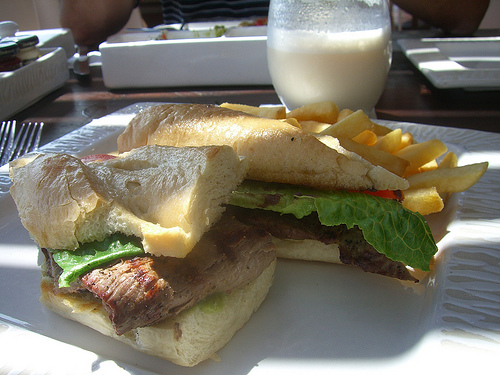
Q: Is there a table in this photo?
A: Yes, there is a table.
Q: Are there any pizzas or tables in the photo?
A: Yes, there is a table.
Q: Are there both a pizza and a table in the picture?
A: No, there is a table but no pizzas.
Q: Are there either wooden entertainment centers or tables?
A: Yes, there is a wood table.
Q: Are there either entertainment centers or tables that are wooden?
A: Yes, the table is wooden.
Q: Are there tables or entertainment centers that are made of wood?
A: Yes, the table is made of wood.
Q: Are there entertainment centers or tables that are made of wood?
A: Yes, the table is made of wood.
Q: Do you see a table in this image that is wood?
A: Yes, there is a wood table.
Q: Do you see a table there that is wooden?
A: Yes, there is a table that is wooden.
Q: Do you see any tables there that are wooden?
A: Yes, there is a table that is wooden.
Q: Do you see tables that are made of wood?
A: Yes, there is a table that is made of wood.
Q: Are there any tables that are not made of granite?
A: Yes, there is a table that is made of wood.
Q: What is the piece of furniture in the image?
A: The piece of furniture is a table.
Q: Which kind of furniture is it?
A: The piece of furniture is a table.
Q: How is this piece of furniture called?
A: This is a table.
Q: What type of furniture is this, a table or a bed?
A: This is a table.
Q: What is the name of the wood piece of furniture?
A: The piece of furniture is a table.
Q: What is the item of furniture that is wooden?
A: The piece of furniture is a table.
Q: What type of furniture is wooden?
A: The furniture is a table.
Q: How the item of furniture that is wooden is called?
A: The piece of furniture is a table.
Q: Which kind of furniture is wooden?
A: The furniture is a table.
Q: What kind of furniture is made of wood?
A: The furniture is a table.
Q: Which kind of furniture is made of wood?
A: The furniture is a table.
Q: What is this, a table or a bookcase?
A: This is a table.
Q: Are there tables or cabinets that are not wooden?
A: No, there is a table but it is wooden.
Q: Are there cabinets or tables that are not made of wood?
A: No, there is a table but it is made of wood.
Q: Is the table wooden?
A: Yes, the table is wooden.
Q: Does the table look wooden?
A: Yes, the table is wooden.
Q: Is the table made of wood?
A: Yes, the table is made of wood.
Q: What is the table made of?
A: The table is made of wood.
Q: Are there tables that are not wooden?
A: No, there is a table but it is wooden.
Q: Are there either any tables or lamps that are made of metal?
A: No, there is a table but it is made of wood.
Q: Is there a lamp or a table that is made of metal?
A: No, there is a table but it is made of wood.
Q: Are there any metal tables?
A: No, there is a table but it is made of wood.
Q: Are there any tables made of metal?
A: No, there is a table but it is made of wood.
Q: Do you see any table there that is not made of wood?
A: No, there is a table but it is made of wood.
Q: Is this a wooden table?
A: Yes, this is a wooden table.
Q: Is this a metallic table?
A: No, this is a wooden table.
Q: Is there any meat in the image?
A: Yes, there is meat.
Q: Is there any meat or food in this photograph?
A: Yes, there is meat.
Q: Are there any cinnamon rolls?
A: No, there are no cinnamon rolls.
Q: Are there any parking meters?
A: No, there are no parking meters.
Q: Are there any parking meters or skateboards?
A: No, there are no parking meters or skateboards.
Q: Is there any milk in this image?
A: Yes, there is milk.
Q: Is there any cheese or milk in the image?
A: Yes, there is milk.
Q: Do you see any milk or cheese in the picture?
A: Yes, there is milk.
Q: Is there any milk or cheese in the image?
A: Yes, there is milk.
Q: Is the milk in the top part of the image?
A: Yes, the milk is in the top of the image.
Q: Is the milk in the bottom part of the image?
A: No, the milk is in the top of the image.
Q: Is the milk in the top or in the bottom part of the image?
A: The milk is in the top of the image.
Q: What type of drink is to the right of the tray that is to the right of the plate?
A: The drink is milk.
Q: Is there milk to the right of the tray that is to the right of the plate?
A: Yes, there is milk to the right of the tray.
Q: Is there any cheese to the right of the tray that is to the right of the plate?
A: No, there is milk to the right of the tray.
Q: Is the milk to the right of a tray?
A: Yes, the milk is to the right of a tray.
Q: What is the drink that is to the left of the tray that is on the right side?
A: The drink is milk.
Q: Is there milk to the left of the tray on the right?
A: Yes, there is milk to the left of the tray.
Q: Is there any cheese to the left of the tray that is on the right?
A: No, there is milk to the left of the tray.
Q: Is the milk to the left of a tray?
A: Yes, the milk is to the left of a tray.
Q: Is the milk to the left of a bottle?
A: No, the milk is to the left of a tray.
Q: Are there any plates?
A: Yes, there is a plate.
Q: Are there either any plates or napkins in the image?
A: Yes, there is a plate.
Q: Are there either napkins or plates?
A: Yes, there is a plate.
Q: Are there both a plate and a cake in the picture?
A: No, there is a plate but no cakes.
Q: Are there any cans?
A: No, there are no cans.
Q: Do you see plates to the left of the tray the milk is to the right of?
A: Yes, there is a plate to the left of the tray.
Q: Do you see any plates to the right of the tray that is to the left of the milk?
A: No, the plate is to the left of the tray.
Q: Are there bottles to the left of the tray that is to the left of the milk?
A: No, there is a plate to the left of the tray.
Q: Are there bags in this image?
A: No, there are no bags.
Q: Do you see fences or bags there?
A: No, there are no bags or fences.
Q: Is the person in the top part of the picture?
A: Yes, the person is in the top of the image.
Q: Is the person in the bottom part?
A: No, the person is in the top of the image.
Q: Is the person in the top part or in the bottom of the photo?
A: The person is in the top of the image.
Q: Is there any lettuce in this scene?
A: Yes, there is lettuce.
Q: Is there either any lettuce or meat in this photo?
A: Yes, there is lettuce.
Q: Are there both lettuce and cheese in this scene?
A: No, there is lettuce but no cheese.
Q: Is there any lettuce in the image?
A: Yes, there is lettuce.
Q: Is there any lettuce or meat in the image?
A: Yes, there is lettuce.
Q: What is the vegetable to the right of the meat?
A: The vegetable is lettuce.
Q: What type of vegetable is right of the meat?
A: The vegetable is lettuce.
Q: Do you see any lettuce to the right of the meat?
A: Yes, there is lettuce to the right of the meat.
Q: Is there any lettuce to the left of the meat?
A: No, the lettuce is to the right of the meat.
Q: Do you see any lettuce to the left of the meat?
A: No, the lettuce is to the right of the meat.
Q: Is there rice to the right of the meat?
A: No, there is lettuce to the right of the meat.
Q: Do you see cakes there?
A: No, there are no cakes.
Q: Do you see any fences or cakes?
A: No, there are no cakes or fences.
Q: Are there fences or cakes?
A: No, there are no cakes or fences.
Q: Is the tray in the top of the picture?
A: Yes, the tray is in the top of the image.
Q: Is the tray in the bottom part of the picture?
A: No, the tray is in the top of the image.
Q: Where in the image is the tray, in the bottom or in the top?
A: The tray is in the top of the image.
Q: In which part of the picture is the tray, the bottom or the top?
A: The tray is in the top of the image.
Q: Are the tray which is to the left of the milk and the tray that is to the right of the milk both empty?
A: Yes, both the tray and the tray are empty.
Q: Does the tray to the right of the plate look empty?
A: Yes, the tray is empty.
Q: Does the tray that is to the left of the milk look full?
A: No, the tray is empty.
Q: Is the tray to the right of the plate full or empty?
A: The tray is empty.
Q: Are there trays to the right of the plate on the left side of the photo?
A: Yes, there is a tray to the right of the plate.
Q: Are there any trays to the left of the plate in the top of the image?
A: No, the tray is to the right of the plate.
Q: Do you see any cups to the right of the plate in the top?
A: No, there is a tray to the right of the plate.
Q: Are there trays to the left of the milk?
A: Yes, there is a tray to the left of the milk.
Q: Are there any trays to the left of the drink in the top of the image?
A: Yes, there is a tray to the left of the milk.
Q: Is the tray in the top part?
A: Yes, the tray is in the top of the image.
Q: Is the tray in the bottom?
A: No, the tray is in the top of the image.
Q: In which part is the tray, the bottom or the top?
A: The tray is in the top of the image.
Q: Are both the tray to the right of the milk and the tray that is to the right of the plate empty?
A: Yes, both the tray and the tray are empty.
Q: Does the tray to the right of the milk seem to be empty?
A: Yes, the tray is empty.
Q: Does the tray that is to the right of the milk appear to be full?
A: No, the tray is empty.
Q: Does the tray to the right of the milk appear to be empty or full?
A: The tray is empty.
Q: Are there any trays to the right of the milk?
A: Yes, there is a tray to the right of the milk.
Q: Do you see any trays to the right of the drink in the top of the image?
A: Yes, there is a tray to the right of the milk.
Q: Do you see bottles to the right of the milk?
A: No, there is a tray to the right of the milk.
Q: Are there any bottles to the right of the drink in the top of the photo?
A: No, there is a tray to the right of the milk.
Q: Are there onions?
A: No, there are no onions.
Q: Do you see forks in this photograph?
A: Yes, there is a fork.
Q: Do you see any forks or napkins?
A: Yes, there is a fork.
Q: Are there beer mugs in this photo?
A: No, there are no beer mugs.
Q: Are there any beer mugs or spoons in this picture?
A: No, there are no beer mugs or spoons.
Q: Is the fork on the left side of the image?
A: Yes, the fork is on the left of the image.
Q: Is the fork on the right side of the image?
A: No, the fork is on the left of the image.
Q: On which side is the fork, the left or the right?
A: The fork is on the left of the image.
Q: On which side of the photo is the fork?
A: The fork is on the left of the image.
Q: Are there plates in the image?
A: Yes, there is a plate.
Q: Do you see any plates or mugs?
A: Yes, there is a plate.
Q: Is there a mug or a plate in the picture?
A: Yes, there is a plate.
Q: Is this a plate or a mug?
A: This is a plate.